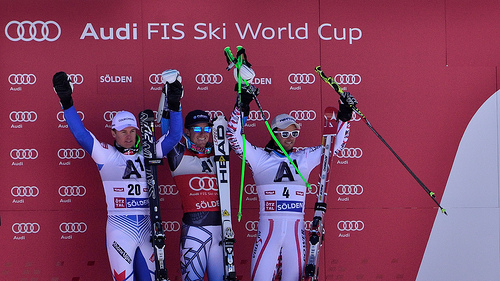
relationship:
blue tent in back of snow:
[381, 79, 494, 126] [443, 119, 498, 278]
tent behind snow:
[492, 73, 499, 101] [425, 82, 498, 275]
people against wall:
[16, 57, 358, 278] [27, 18, 485, 271]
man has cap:
[168, 110, 232, 265] [111, 110, 140, 131]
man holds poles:
[36, 71, 179, 279] [196, 36, 337, 272]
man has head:
[52, 68, 184, 280] [109, 112, 138, 147]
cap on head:
[109, 110, 138, 132] [109, 112, 138, 147]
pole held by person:
[313, 65, 449, 216] [220, 79, 353, 279]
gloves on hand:
[49, 72, 80, 112] [47, 65, 95, 119]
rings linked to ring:
[4, 19, 366, 233] [4, 17, 23, 41]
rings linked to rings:
[4, 19, 366, 233] [48, 215, 92, 237]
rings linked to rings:
[4, 218, 51, 241] [5, 176, 47, 208]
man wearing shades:
[161, 68, 259, 281] [190, 125, 218, 133]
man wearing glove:
[52, 68, 184, 280] [50, 67, 75, 111]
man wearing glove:
[52, 68, 184, 280] [335, 89, 357, 120]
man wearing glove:
[52, 68, 184, 280] [233, 84, 256, 116]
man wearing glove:
[52, 68, 184, 280] [161, 79, 185, 110]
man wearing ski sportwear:
[52, 68, 184, 280] [109, 213, 163, 255]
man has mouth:
[52, 68, 184, 280] [123, 138, 133, 142]